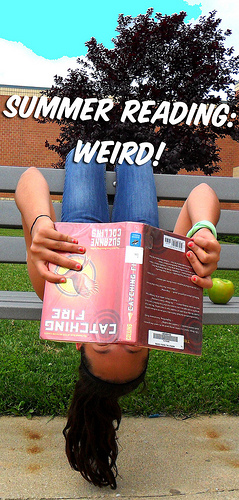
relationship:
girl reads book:
[62, 132, 161, 405] [44, 309, 118, 338]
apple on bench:
[206, 274, 237, 308] [159, 175, 233, 200]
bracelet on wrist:
[14, 209, 213, 258] [28, 217, 64, 238]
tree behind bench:
[36, 55, 201, 177] [159, 175, 233, 200]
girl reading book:
[62, 132, 161, 405] [44, 309, 118, 338]